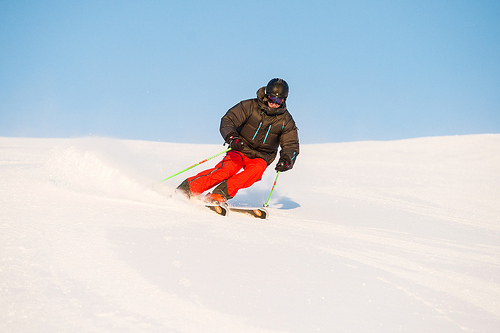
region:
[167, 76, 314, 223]
a person skiing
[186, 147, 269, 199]
red and black pants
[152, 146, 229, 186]
red and green ski pole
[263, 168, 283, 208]
red and green ski pole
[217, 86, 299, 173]
black puffy jacket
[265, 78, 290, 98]
black helmet on a person's head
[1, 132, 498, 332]
a white blanket of snow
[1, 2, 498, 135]
a clear blue sky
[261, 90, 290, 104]
ski goggles on a person's face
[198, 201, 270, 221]
black and red skis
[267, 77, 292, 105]
a black helmet on a skier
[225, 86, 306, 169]
a black coat on a skier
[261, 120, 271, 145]
a blue string on a coat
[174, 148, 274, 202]
orange pants on a skier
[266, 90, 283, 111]
the face of a skier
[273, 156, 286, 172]
a black glove on a skier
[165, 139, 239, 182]
a yellow ski pole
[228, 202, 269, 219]
a black and white ski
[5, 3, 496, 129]
a beautiful blue ski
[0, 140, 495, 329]
a white snowy slope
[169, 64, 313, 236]
A person skiing downhill.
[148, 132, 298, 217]
Green ski poles in the person's hands.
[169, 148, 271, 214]
Red ski pants on the person.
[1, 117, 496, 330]
The ground is white.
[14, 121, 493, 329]
There is snow on the ground.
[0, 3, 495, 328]
Photo taken during the winter.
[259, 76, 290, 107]
The skier is wearing a helmet.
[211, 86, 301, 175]
The jacket is black.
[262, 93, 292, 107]
Goggles on the person's face.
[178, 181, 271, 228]
Skis on the skier's feet.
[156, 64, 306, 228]
person skiing on a slope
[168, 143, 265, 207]
orange and black snow pants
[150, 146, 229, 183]
bright green ski stick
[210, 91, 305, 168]
black puffy winter jacket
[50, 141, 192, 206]
white snow being kicked up by the ski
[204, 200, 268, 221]
two long think skis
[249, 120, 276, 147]
two blue stripes on the black jacket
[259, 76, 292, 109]
black helmet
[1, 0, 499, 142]
clear blue sky with no cloud in sight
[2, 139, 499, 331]
white snow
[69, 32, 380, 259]
a skier on the snow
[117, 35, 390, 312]
a person skiing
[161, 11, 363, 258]
a person wearing orange pants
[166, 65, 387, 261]
a skier wearing orange pants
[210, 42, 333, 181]
a person wearing a brown jacket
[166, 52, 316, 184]
a skier wearing a brown jacket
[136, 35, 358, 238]
a skier on snow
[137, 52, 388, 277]
a person on snow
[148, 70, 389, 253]
a person leaning to the side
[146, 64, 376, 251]
a skier leaning to the side